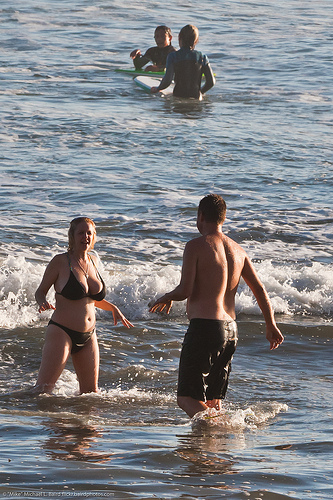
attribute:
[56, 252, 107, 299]
bikini top — black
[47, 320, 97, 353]
bikini bottom — black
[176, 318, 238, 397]
swim trunks — black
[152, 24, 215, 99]
boy — surfing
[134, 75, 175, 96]
surfboard — floating, white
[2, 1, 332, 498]
water — foamy, ocean, calm, blue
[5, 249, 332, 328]
wave — crashing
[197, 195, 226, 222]
hair — short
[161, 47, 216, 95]
wet suit — black, blue